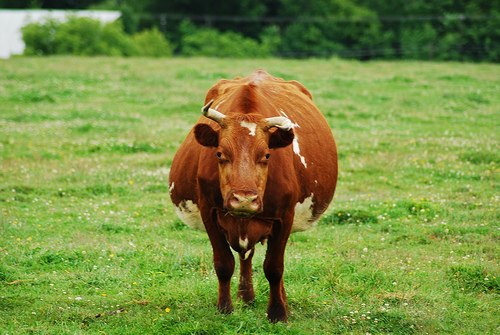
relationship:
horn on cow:
[196, 95, 294, 140] [160, 63, 352, 313]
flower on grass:
[129, 279, 140, 288] [0, 186, 130, 330]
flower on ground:
[121, 270, 147, 293] [90, 175, 162, 326]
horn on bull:
[200, 96, 232, 129] [168, 66, 339, 324]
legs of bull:
[190, 221, 337, 310] [104, 60, 406, 304]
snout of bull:
[219, 190, 267, 218] [162, 64, 344, 324]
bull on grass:
[168, 66, 339, 324] [281, 259, 360, 331]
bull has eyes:
[168, 66, 339, 324] [213, 146, 280, 167]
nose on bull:
[227, 192, 257, 203] [168, 66, 339, 324]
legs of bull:
[203, 221, 237, 312] [168, 66, 339, 324]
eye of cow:
[207, 145, 239, 176] [136, 60, 394, 300]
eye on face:
[207, 145, 239, 176] [215, 139, 271, 214]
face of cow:
[215, 139, 271, 214] [136, 60, 394, 300]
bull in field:
[162, 64, 344, 324] [6, 50, 476, 332]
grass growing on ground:
[373, 146, 480, 293] [0, 55, 498, 333]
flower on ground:
[129, 279, 140, 288] [0, 55, 498, 333]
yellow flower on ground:
[425, 198, 433, 203] [0, 55, 498, 333]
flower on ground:
[334, 208, 348, 219] [345, 163, 372, 181]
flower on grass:
[129, 279, 140, 288] [10, 140, 121, 226]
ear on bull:
[192, 122, 217, 149] [168, 66, 339, 324]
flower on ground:
[129, 279, 140, 288] [3, 256, 206, 330]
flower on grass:
[129, 279, 140, 288] [1, 50, 496, 330]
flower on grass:
[334, 208, 348, 219] [347, 231, 495, 331]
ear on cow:
[266, 125, 298, 152] [172, 70, 339, 316]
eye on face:
[252, 150, 272, 166] [195, 107, 281, 217]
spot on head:
[226, 110, 266, 155] [184, 85, 304, 235]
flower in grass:
[334, 208, 348, 219] [318, 261, 485, 333]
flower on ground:
[375, 115, 443, 207] [33, 53, 495, 315]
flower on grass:
[129, 279, 140, 288] [14, 77, 174, 331]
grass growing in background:
[0, 54, 500, 334] [114, 43, 408, 79]